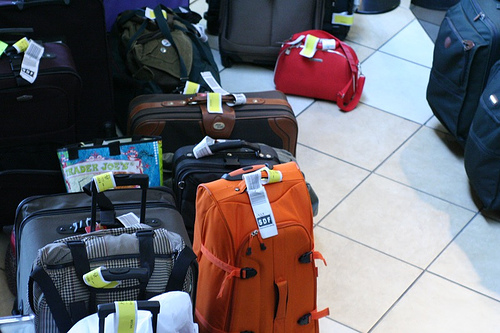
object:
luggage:
[192, 162, 329, 332]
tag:
[242, 171, 278, 240]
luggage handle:
[91, 172, 148, 231]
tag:
[92, 171, 117, 193]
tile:
[370, 271, 499, 332]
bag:
[274, 28, 366, 111]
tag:
[300, 34, 319, 58]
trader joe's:
[65, 162, 127, 177]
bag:
[55, 133, 163, 192]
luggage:
[127, 92, 297, 157]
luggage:
[464, 60, 499, 213]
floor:
[0, 0, 499, 333]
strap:
[200, 244, 246, 299]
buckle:
[239, 265, 257, 280]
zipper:
[17, 202, 184, 250]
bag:
[27, 224, 199, 332]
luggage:
[15, 172, 192, 316]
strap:
[291, 29, 365, 112]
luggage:
[67, 290, 199, 332]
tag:
[207, 92, 224, 114]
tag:
[115, 299, 138, 332]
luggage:
[0, 37, 83, 234]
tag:
[19, 38, 44, 83]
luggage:
[426, 0, 499, 142]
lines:
[421, 269, 498, 305]